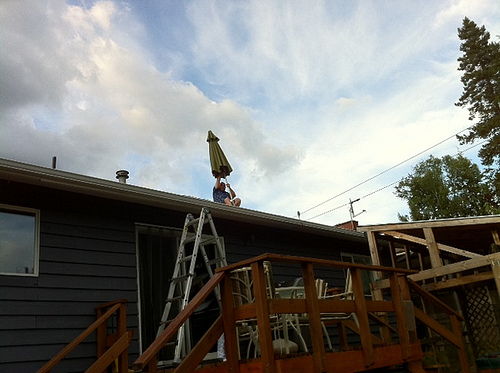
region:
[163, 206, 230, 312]
a stainless ladder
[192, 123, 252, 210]
a man holding an umbrella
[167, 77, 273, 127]
a white clouds in the sky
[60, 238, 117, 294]
the house wall is painted into grey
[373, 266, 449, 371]
a stairs that is made of wood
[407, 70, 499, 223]
trees at the right side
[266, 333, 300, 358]
a white box under the table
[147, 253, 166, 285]
the curtain is color white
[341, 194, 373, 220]
the top part of the electrical post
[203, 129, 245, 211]
a man holding a large umbrella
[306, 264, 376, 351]
a plastic chair on a wooden floor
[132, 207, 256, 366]
a large metal ladder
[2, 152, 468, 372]
a dark grey colored house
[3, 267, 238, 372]
a set of wooden stairs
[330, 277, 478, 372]
a set of wooden stairs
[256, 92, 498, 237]
a long line of electric wires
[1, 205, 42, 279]
a window on a house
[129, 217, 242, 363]
a large glass door for a house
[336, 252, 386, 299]
a window on a house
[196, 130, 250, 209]
a man on the roof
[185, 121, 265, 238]
a man on the roof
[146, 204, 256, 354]
a metal silver ladder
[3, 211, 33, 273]
a window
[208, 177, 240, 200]
man on the roof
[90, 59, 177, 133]
the clouds are white in the sky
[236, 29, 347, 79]
clouds are in the sky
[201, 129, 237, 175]
a closed umbrella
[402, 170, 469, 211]
the green tree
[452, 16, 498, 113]
a tall tree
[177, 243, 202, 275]
a ladder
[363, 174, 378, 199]
electrical lines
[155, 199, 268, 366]
this is a ladder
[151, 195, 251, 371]
the ladder is silver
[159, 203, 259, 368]
a metal ladder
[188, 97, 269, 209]
he is holding an umbrella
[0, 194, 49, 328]
here is a window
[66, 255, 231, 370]
the railing is made of wood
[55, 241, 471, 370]
a wooden deck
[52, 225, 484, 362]
the deck is made of wood